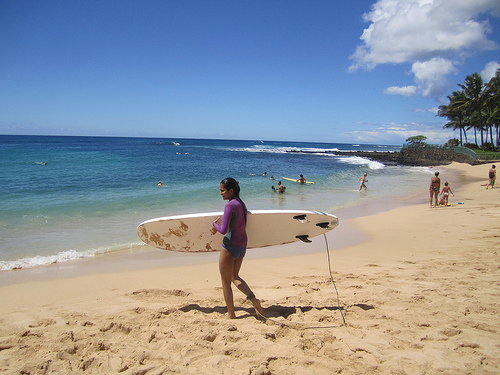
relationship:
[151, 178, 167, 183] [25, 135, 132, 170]
person in water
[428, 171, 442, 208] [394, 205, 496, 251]
people standing on beach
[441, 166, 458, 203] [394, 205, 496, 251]
child standing on beach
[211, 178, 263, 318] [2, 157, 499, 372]
girl standing on sand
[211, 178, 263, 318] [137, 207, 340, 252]
girl with surfboard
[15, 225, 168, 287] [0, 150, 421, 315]
wave rolling up shore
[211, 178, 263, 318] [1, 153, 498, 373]
girl walking on beach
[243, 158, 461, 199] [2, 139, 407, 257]
people in water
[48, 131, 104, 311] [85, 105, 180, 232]
distant waves crashing against beach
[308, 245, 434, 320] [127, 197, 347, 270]
sand stained surfboard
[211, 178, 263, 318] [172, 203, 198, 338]
girl carrying surfboard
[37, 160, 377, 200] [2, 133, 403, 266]
people in water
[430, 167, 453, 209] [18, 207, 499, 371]
people standing in sand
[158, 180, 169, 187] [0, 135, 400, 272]
person swimming in ocean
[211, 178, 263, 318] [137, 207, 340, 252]
girl carrying a surfboard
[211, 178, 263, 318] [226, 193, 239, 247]
girl wearing a purple bathing suit top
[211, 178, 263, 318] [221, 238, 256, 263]
girl wearing bikini bottoms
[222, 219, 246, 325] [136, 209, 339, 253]
girl has a lanyard connected to her board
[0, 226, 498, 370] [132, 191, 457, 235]
sand stuck to bottom of surfboard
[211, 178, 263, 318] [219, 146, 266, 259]
girl has dark colored hair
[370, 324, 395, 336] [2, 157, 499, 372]
footprints in sand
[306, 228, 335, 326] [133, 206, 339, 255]
string hanging down from board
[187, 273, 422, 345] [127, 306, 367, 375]
footprints in sand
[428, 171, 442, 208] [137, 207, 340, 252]
people on a surfboard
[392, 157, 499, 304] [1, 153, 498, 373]
three people walking on beach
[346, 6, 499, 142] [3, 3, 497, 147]
clouds in sky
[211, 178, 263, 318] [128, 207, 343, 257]
girl carrying a surfboard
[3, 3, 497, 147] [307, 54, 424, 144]
sky with a few clouds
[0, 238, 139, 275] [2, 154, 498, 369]
wave lapping up on shore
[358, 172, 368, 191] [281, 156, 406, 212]
people running out of water